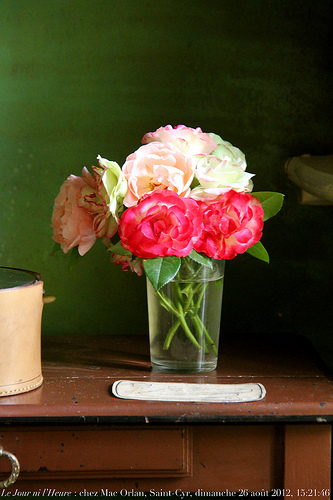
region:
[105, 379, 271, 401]
White dish in front of flowers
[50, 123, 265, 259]
Eight flowers in the cup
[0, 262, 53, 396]
Wooden desk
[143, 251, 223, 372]
Glass cup holding water and flowers.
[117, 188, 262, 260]
Two hot pink flowers in the cup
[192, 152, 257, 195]
One white flower in the cup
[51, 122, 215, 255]
Three light pink flowers in the cup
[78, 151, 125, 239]
One green and red flower in the cup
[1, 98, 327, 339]
Green wall behind the flowers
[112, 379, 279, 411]
PIECE OF WHITE PAPER IS IN FRONT OF VASE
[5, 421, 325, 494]
FRONT OF TABLE IS BROWN IN COLOR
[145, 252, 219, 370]
VASE IS A CLEAR COLOR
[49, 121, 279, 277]
FLOWERS IN VASE ARE PINK AND PALES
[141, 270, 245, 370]
STEMS IN VASE ARE COVERED IN WATER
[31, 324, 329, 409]
TABLE TOP IS A BROWN COLOR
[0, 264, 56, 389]
A PINK CONTAINER IS TO THE LEFT OF FLOWERS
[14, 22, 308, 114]
WALL IN BACKGROUND IS GREEN IN COLOR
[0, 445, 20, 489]
SILVER HANDLE IS ON FRONT OF DRAWER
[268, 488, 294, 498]
PICTURE WAS TAKEN IN 2012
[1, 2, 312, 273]
The wall is green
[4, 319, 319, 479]
A brown wooden desk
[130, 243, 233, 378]
A glass vase on desk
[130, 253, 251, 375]
Glass vase filled with water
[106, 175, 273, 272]
Two bright pink flowers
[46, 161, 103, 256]
Light pink rose in vase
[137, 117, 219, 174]
White rose with pink outlines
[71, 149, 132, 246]
White rose with red outlines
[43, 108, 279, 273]
Nine roses can be seen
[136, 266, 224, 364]
Rose stems in water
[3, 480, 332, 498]
printed copyright of a photographer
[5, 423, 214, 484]
drawer of a wooden table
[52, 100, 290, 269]
flowers in a vase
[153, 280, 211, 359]
stems of the flowers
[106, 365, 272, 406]
paper on the table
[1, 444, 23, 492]
knob on a drawer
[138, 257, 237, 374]
glass of water with flowers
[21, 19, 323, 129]
green wall in the background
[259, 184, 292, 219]
leaf of a flower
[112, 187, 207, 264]
bright pink flower in glass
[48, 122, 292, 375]
Flowers in a glass of water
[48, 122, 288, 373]
Cut roses displayed in a glass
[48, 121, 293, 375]
Cut flowers in a glass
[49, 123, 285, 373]
Roses in a glass of water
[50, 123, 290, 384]
Roses displayed on a table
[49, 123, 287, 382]
Pink flowers displayed on a table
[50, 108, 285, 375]
Green stems in water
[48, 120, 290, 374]
Fresh flowers in water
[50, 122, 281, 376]
Pink flowers in a glass of water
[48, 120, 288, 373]
Multiple pink colored displayed